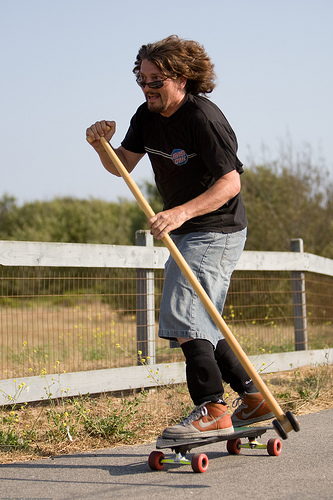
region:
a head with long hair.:
[121, 34, 233, 123]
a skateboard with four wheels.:
[144, 408, 287, 478]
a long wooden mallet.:
[87, 131, 306, 442]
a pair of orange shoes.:
[162, 395, 239, 447]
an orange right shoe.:
[226, 386, 284, 436]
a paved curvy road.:
[0, 403, 332, 498]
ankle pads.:
[160, 340, 228, 431]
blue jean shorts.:
[136, 216, 264, 374]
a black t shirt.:
[119, 94, 249, 248]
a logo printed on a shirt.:
[143, 145, 194, 172]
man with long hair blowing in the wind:
[124, 26, 224, 128]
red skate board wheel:
[190, 447, 219, 478]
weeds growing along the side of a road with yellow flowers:
[29, 344, 132, 439]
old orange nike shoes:
[154, 410, 248, 449]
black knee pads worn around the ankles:
[170, 328, 230, 407]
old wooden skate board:
[133, 400, 286, 489]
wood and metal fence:
[11, 227, 141, 390]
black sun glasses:
[134, 65, 177, 94]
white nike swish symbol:
[197, 412, 235, 434]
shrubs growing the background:
[244, 134, 323, 244]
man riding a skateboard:
[69, 36, 310, 464]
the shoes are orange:
[153, 388, 293, 466]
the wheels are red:
[142, 437, 291, 479]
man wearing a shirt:
[104, 90, 282, 250]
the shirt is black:
[109, 98, 294, 274]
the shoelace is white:
[169, 394, 218, 446]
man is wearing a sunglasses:
[115, 62, 210, 121]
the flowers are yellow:
[107, 341, 158, 379]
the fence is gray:
[10, 205, 137, 431]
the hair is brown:
[139, 36, 219, 95]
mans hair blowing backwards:
[142, 38, 217, 96]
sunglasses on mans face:
[128, 70, 172, 96]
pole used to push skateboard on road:
[85, 124, 295, 440]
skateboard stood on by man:
[139, 384, 284, 478]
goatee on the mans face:
[137, 91, 168, 111]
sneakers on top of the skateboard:
[156, 393, 283, 437]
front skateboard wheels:
[143, 443, 224, 478]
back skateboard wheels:
[225, 430, 293, 459]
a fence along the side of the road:
[3, 231, 323, 368]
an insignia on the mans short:
[164, 143, 194, 172]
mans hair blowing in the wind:
[100, 41, 250, 93]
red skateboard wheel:
[184, 458, 220, 482]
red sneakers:
[196, 402, 237, 437]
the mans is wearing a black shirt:
[134, 103, 276, 249]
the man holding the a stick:
[83, 128, 323, 406]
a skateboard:
[156, 400, 298, 475]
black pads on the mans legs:
[175, 334, 237, 408]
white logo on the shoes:
[197, 414, 226, 426]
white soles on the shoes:
[201, 429, 236, 437]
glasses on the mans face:
[134, 77, 173, 91]